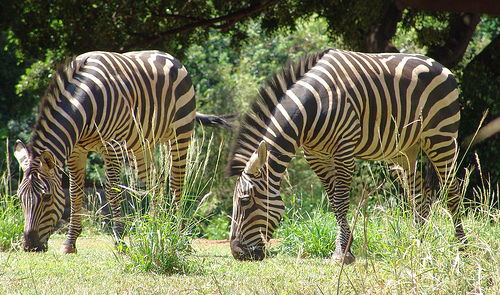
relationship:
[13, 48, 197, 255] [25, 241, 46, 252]
zebra has a mouth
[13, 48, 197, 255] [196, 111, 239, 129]
zebra has a tail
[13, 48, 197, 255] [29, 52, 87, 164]
zebra has a mane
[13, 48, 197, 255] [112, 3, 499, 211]
zebra in front of a tree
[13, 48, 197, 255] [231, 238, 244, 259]
zebra has a nose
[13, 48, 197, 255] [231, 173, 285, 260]
zebra has a head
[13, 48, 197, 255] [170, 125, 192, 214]
zebra has a leg